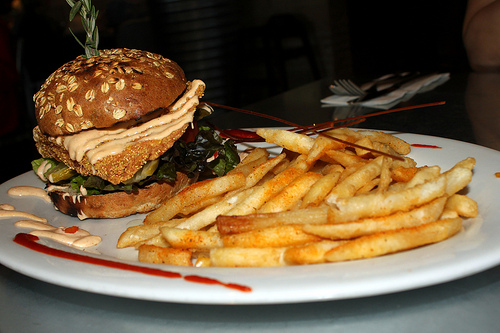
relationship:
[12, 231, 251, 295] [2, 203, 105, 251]
ketchup and dressing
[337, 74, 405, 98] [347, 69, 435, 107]
fork and knife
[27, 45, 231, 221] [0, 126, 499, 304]
sandwich on plate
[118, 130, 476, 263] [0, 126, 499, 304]
fries on plate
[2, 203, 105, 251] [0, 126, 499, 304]
dressing on plate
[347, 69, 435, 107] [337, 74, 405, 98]
knife and fork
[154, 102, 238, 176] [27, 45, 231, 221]
lettuce on sandwich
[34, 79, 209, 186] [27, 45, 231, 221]
meat on sandwich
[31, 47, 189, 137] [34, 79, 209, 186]
bun on meat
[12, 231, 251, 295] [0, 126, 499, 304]
ketchup on plate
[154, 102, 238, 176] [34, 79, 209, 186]
lettuce on meat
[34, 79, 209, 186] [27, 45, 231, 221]
meat in sandwich